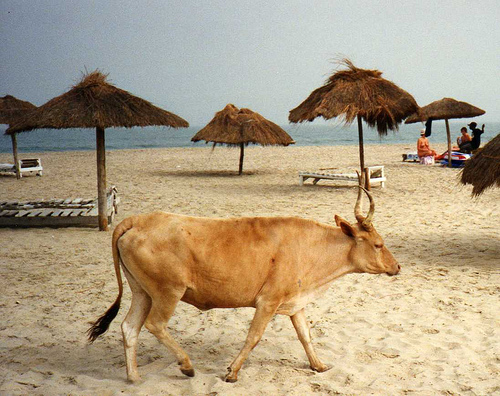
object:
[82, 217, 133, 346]
tail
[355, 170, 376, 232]
horns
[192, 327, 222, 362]
sand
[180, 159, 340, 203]
sand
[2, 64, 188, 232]
umbrella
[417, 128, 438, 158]
people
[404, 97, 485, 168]
umbrella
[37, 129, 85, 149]
water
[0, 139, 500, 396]
beach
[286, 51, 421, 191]
umbrella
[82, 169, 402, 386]
cow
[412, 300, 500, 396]
sand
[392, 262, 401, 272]
nose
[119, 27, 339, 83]
sky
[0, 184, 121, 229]
chairs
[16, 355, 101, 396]
sand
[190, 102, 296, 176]
umbrellas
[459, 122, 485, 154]
people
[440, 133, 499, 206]
umbrella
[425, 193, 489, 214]
sand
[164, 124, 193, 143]
water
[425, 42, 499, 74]
sky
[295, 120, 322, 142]
water